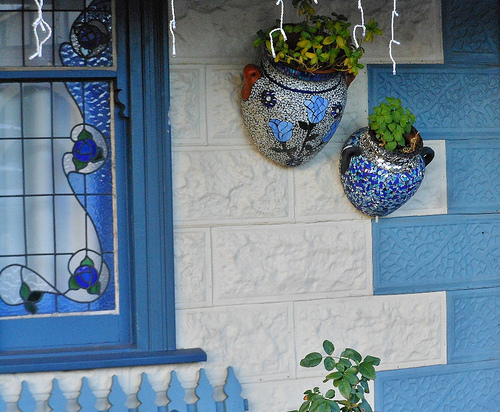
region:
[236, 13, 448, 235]
vases with green plants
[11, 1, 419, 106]
white hanging christmas lights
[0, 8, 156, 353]
blue flowers on a glass window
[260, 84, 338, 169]
picture of blue flowers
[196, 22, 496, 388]
blue and white wall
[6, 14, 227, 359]
window with a blue sill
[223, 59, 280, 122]
small brown handle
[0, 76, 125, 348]
window with many panes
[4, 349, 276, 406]
top of a blue fence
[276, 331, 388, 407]
top of a plant with small leaves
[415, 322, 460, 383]
the tile is blue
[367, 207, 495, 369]
the tile is blue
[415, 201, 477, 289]
the tile is blue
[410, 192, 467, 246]
the tile is blue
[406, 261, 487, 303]
the tile is blue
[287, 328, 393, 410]
green leaf like plant on bottom of picture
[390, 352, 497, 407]
blue textured tile on right side of picture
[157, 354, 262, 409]
light blue decorative fence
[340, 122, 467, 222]
jug like vase mounted to wall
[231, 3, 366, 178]
jug like vase with tile flowers mounted on wall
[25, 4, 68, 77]
white hanging christmas lights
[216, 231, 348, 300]
white textured till on wall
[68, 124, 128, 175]
blue stain glass rose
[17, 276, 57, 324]
green stain glass leaves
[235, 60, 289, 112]
red handles on jug like vase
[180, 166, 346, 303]
White bricks on wall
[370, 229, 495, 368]
Blue bricks on the wall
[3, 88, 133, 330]
A window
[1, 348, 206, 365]
A blue window seal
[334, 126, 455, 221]
A blue and grey pot on the wall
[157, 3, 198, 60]
white lights hanging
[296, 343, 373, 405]
Green plant leaves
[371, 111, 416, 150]
Green leaves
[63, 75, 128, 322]
Decoration on the window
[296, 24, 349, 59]
Green and yellow leaves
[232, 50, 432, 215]
Small vases on wall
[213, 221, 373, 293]
White brick is rough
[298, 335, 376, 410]
Small green plant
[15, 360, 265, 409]
Top of fence is blue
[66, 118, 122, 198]
Rose in stained glass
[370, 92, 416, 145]
Small green plant in pot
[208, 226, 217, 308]
Cleft between brick facade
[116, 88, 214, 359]
Edge of window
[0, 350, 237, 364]
Blue window sill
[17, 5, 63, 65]
Icicle lights are hanging